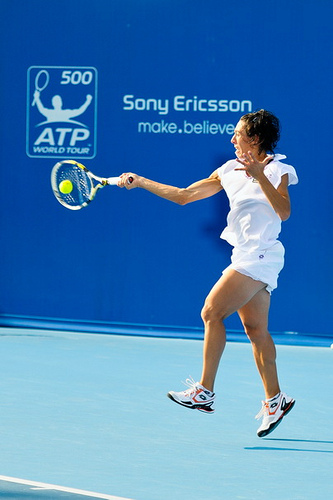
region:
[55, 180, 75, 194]
a small green tennis ball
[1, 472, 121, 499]
a long white line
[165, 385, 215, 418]
a woman's tennis shoe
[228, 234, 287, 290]
a woman's white shorts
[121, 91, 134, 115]
a white capital letter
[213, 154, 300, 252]
a woman's white shirt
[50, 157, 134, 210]
a black, white and yellow racket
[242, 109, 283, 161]
a woman's black hair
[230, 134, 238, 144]
the nose of a woman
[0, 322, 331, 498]
part of a tennis court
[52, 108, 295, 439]
a person jumping up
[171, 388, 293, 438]
white, black, and red shoes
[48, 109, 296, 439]
a tennis player swinging racket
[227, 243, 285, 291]
short white tennis shorts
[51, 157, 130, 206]
a white and yellow tennis racket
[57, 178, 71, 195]
a green tennis ball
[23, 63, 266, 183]
white writing on blue wall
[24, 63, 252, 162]
white advertisement logos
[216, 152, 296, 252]
a white short sleeve shirt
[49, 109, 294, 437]
a man in a white uniform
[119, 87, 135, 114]
White letter on board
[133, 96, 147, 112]
White letter on board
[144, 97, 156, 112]
White letter on board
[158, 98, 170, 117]
White letter on board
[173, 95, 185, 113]
White letter on board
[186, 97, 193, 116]
White letter on board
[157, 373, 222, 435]
White and black shoe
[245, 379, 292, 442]
White and black shoe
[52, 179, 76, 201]
Bright yellow tennis ball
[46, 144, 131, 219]
Yellow and white tennis racket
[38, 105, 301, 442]
tennis player hitting a ball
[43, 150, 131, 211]
a tennis ball on a racket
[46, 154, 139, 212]
racket is white and yellow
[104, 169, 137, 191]
handle of racket is white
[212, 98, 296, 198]
woman has black hair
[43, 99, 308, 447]
woman jumps in the air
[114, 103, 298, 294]
woman wears white cloths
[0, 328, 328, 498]
floor of tennis court is blue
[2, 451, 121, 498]
a white line on tennis cout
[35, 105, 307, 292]
woman holds a racket with right hand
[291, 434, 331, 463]
shadow on the tennis court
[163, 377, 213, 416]
shoes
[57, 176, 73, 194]
tennis ball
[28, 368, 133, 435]
outbound of the tennis court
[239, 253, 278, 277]
white shorts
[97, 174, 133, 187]
women is holding a tennis racket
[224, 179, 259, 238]
a white shirt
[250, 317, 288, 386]
the womens leg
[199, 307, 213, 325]
the womens knee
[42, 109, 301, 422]
lady is hitting a tennis ball